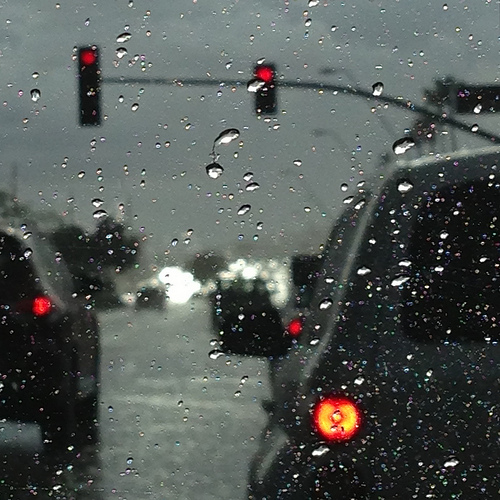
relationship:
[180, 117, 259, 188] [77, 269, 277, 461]
rain on highway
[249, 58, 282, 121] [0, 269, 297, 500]
traffic light on highway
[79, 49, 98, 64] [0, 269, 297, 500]
lights on highway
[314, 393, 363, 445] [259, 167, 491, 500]
brake lights on car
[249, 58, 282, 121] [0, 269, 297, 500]
street light on highway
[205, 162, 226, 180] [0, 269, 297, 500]
rain drops on highway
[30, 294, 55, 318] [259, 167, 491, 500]
lights on car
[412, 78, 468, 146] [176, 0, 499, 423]
trees in background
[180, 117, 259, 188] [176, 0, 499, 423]
water on camera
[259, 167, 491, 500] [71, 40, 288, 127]
car stopped at lights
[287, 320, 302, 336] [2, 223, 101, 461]
headlights on car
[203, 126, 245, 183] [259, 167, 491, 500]
rain drops on car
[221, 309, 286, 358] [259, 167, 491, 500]
side mirror on car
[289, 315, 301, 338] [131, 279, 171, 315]
headlights in distance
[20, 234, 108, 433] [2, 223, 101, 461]
side of vehicle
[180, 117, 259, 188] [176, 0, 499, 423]
rain on outside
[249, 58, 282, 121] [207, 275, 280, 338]
red light behind vehicle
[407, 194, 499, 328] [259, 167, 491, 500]
window of vehicle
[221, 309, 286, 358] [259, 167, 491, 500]
mirror on vehicle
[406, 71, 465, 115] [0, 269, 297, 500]
tree tops above highway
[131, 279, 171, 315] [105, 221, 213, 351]
vehicle in distant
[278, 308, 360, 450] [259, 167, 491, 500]
brake lights on car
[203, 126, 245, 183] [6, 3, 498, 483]
rain droplets on camera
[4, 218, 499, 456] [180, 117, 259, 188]
traffic in rain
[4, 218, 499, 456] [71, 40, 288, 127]
traffic at light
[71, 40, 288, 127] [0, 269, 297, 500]
street lamps on highway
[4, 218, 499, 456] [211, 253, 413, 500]
cars in row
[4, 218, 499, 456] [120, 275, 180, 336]
traffic moving forward